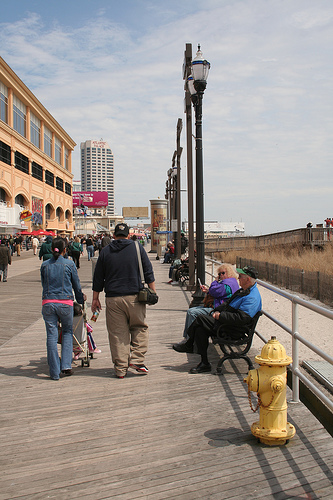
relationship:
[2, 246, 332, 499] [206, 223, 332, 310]
boardwalk near beach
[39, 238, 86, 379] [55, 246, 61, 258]
woman has a ponytail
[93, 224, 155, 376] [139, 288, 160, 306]
man has a camera bag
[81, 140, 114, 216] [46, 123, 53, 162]
building has a window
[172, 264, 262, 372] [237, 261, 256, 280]
man wearing a hat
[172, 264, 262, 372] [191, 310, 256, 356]
man wearing pants